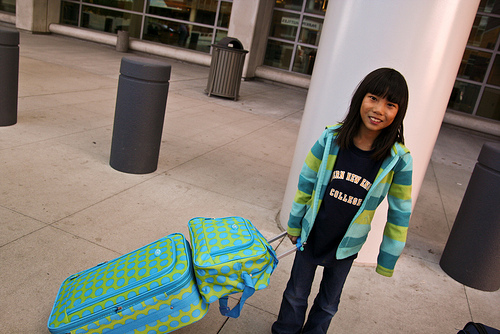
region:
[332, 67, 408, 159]
The girl has a smile and has dark hair.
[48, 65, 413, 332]
The girl is holding a suitcase bigger than she is.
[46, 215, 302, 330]
The suitcase is blue and yellow.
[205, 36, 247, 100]
The trash can has vertical llines.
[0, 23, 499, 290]
Three gray cylinders are behind the girl.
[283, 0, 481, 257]
A large white column is behind girl.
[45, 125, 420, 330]
The jacket and luggage match colors.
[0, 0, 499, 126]
Seventeen window panels appear to be in the background.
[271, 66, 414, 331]
The girl is wearing tones of blue and yellow.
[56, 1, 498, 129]
Reflections are in the glass windowpanes.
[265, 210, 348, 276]
girl holding handle on luggage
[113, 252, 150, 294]
polka dots on the luggage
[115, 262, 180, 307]
luggage is lime green and bright blue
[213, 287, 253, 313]
blue strap on the luggage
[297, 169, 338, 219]
girl is wearing a jacket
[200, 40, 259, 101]
trash can on the walkway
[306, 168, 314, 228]
stripes on the jacket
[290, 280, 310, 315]
girl is wearing jeans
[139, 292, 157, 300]
blue zipper on the luggage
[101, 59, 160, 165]
black pole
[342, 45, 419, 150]
Head of a person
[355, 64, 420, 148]
Head of a lady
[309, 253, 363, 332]
Leg of a person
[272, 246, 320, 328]
Leg of a person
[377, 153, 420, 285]
Hand of a person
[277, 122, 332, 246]
Hand of a person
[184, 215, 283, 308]
This is a bag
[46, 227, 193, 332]
This is a bag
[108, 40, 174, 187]
This is a dust bin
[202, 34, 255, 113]
This is a dust bin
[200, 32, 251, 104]
trash barrel outside airport on sidewalk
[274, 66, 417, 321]
young girl with blue and green jacket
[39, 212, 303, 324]
blue and green suitcases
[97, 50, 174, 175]
black pillar on a sidewalk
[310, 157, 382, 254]
black shirt with white letters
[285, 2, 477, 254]
white pillar on a sidewalk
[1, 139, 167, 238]
square pavers in a sidewalk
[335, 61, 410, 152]
head of girl with long black hair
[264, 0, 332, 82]
window in an airport next to sidewalk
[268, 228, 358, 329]
young girl wearing black pants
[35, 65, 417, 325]
young girl with luggage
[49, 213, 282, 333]
teal and lime green luggage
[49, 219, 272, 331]
green suitcase with blue polka dots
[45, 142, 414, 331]
sweater and suitcase match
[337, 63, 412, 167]
young girl with black hair and bangs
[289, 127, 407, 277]
blue and green hooded sweatshirt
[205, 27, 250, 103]
trash can by building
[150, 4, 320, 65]
window of airport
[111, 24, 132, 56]
ashtray for smokers by window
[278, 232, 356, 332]
jeans worn by young girl